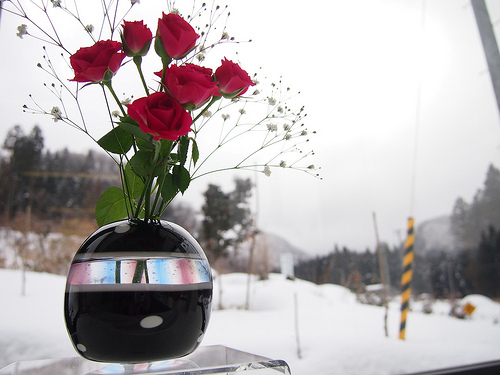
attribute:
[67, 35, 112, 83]
rose — red, pink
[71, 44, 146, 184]
flower — small, red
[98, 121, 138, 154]
leaf — green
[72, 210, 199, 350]
vase — black, beautiful, silver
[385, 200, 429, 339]
pole — black, yellow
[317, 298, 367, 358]
snow — white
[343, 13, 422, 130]
sky — gray, cloudy, clear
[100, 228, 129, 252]
light — shining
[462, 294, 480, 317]
sign — yellow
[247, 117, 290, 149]
flower — white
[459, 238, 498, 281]
tree — green